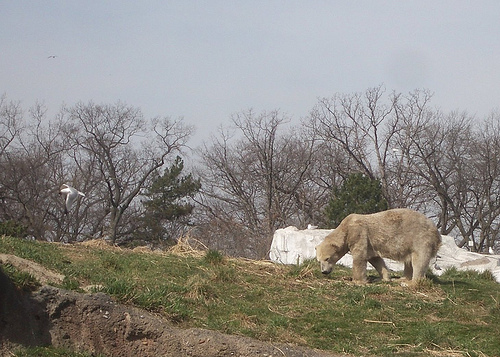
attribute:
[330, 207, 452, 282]
bear — looking, eating, white, polar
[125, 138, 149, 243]
tree — large, brown, bare, here, forest, edge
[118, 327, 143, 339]
dirt — here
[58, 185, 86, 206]
bird — here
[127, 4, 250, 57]
sky — grey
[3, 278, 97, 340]
rock — large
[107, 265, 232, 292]
grass — here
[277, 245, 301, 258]
ice — here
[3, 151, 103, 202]
branch — here